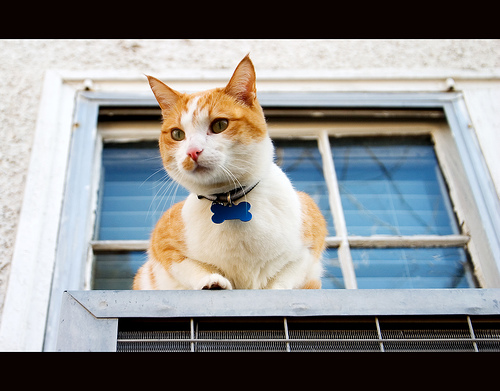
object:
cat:
[133, 52, 328, 293]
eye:
[208, 116, 231, 133]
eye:
[164, 125, 184, 140]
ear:
[222, 51, 259, 102]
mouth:
[186, 161, 214, 176]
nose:
[186, 144, 204, 160]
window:
[327, 134, 468, 243]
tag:
[209, 201, 252, 226]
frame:
[3, 67, 500, 351]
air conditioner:
[40, 290, 500, 353]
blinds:
[93, 135, 470, 289]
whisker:
[143, 154, 189, 213]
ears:
[145, 72, 185, 113]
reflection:
[276, 142, 453, 236]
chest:
[187, 194, 299, 282]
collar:
[197, 181, 261, 203]